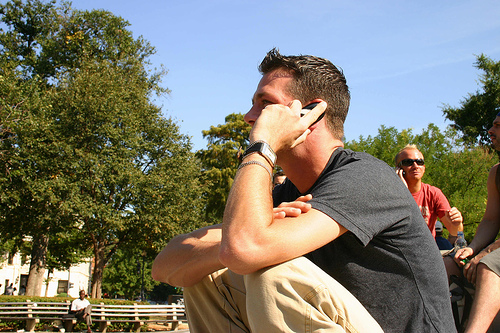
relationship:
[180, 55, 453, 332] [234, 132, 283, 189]
man has wrist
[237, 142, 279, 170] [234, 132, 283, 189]
watch on wrist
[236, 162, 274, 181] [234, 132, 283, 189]
bracelet on wrist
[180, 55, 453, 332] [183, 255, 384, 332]
man has pants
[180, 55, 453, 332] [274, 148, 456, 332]
man has shirt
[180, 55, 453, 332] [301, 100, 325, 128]
man holding phone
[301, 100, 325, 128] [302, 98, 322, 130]
phone held to ear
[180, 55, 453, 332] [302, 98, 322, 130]
man has ear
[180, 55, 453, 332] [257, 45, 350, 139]
man has hair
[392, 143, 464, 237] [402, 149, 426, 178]
man has face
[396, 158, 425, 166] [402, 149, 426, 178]
sunglasses on face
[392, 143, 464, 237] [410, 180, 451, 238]
man wearing shirt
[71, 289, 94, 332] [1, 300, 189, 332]
person sitting on bench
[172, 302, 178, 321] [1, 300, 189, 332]
post on bench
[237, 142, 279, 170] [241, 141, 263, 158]
watch has band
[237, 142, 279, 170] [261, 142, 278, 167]
watch has face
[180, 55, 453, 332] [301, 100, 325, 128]
man has phone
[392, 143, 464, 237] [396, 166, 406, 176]
man has phone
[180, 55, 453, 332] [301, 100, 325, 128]
man talking on phone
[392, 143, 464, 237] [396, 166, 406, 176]
man talking on phone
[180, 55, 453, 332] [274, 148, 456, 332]
man wearing shirt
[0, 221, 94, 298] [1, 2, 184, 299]
building behind tree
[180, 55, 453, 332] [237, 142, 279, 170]
man wearing watch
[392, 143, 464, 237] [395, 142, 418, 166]
man has hair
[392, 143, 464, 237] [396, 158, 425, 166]
man wearing sunglasses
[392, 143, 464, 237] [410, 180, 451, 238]
man in shirt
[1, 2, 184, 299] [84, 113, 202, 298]
tree next to tree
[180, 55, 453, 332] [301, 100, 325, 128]
man on phone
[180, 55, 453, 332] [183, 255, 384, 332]
man wearing pants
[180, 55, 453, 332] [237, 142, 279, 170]
man with watch